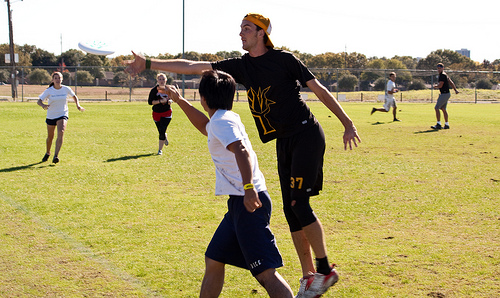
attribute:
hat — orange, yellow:
[244, 10, 278, 49]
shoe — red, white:
[294, 270, 342, 295]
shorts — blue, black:
[209, 197, 283, 274]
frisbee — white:
[81, 40, 116, 69]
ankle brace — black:
[142, 55, 155, 72]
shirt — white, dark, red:
[38, 89, 76, 117]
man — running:
[371, 73, 403, 119]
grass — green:
[3, 99, 499, 280]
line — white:
[11, 193, 155, 296]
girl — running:
[160, 81, 295, 297]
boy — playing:
[158, 67, 296, 297]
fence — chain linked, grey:
[5, 59, 499, 121]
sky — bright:
[21, 2, 499, 93]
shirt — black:
[219, 57, 314, 127]